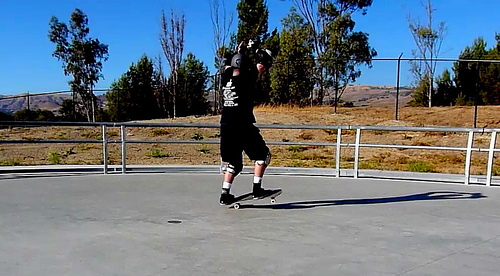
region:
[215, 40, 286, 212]
A person skateboarding.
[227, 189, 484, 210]
The shadow of a skateboarder.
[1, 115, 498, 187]
The metal railing in a skate park.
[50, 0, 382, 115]
Row of trees on the edge of a yard.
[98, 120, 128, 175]
Two metal poles on a railing.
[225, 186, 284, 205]
A grey skateboard.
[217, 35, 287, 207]
A person wearing black shorts.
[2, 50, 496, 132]
The fence surrounding a skate park.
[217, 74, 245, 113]
White wording on a black shirt.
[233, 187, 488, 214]
a long dark shadow on the ground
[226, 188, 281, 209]
a gray colored skateboard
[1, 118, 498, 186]
a silver metal railing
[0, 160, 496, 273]
a concrete skateboarding area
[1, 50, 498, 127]
a chain link fence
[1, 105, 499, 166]
dead brown grass and bare ground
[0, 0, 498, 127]
trees growing on the top of a bank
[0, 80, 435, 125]
hills in the background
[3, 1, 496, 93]
bright blue sky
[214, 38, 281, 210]
a person riding a skateboard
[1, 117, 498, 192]
Grey metal railing of a skate park.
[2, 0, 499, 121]
Trees behind a fence.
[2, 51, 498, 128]
A fence at the edge of a skate park.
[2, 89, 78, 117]
Mountains in the distance.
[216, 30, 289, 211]
A person on a skateboard.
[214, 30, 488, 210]
A man and his shadow.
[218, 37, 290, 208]
Man wearing a skate helmet.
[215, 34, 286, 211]
Man riding a skateboard.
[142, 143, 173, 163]
A plant in a yard.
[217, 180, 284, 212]
Person on a board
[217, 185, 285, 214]
Person is on a board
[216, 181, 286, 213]
Person on a skateboard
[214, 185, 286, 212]
Person is on a skateboard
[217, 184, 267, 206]
Person wearing shoes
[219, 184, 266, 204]
Person is wearing shoes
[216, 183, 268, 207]
Person wearing black shoes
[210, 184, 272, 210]
Person is wearing black shoes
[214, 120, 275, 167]
Person wearing black shoes